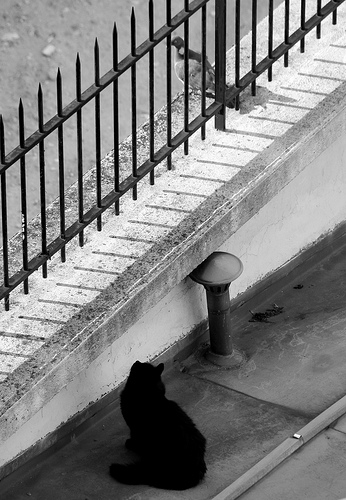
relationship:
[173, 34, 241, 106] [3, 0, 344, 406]
bird on ledge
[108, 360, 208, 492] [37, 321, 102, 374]
cat next to ledge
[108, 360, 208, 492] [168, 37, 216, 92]
cat looks at dove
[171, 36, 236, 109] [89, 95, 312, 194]
bird on ledge